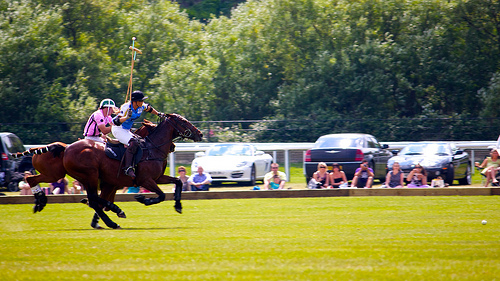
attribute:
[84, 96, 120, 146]
man — polo player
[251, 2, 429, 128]
trees — green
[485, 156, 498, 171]
shirt — green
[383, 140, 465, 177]
car — black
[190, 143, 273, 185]
car — white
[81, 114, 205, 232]
horses — running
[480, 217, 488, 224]
ball — small, white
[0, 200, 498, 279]
grass — green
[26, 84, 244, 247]
people — spectating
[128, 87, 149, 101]
helmet — black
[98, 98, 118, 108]
helmet — black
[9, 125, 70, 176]
hair — braided, bound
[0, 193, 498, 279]
green grass — very short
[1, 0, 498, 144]
leaves — green